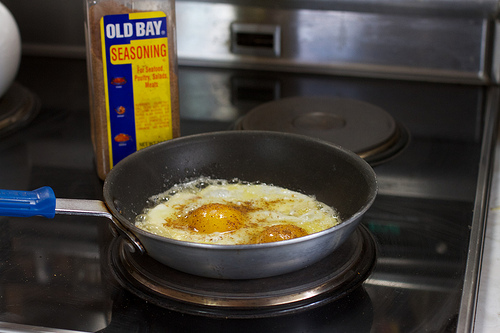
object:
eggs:
[179, 199, 251, 234]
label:
[99, 11, 170, 175]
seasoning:
[84, 0, 178, 181]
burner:
[225, 94, 413, 169]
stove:
[0, 54, 499, 333]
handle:
[0, 186, 103, 218]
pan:
[0, 129, 381, 281]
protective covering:
[0, 186, 58, 219]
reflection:
[175, 1, 372, 67]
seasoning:
[162, 195, 309, 245]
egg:
[245, 220, 313, 244]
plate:
[115, 223, 369, 312]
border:
[449, 81, 498, 332]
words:
[110, 47, 118, 62]